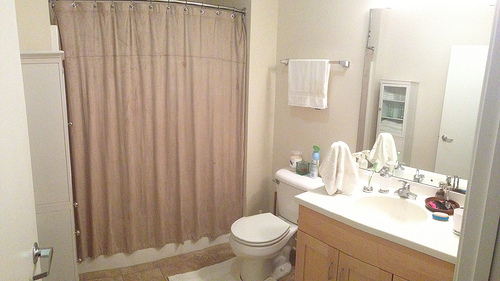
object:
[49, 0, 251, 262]
shower curtain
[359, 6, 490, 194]
mirror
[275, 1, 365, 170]
wall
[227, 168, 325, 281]
toilet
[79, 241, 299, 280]
floor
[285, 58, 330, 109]
towel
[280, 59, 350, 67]
rack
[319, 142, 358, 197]
towel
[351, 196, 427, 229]
sink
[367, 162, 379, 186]
tooth brush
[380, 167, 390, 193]
cup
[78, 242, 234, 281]
mat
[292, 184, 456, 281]
cabinet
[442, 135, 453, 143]
knob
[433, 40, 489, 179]
door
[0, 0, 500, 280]
bathroom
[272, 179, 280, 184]
handle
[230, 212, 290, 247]
seat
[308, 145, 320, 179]
can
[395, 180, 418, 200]
faucet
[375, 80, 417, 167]
storage cabinet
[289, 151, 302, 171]
bottles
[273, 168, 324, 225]
toilet tank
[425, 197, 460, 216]
containers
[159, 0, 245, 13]
bar